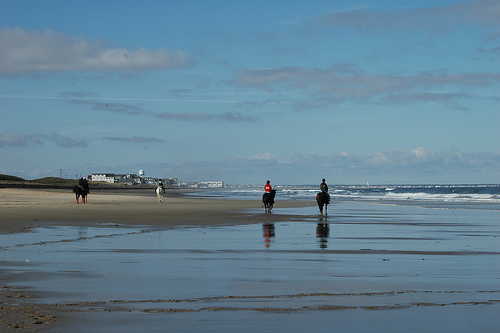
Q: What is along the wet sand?
A: Skid marks.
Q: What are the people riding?
A: Horses.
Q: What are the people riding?
A: Horses.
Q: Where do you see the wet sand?
A: Beach.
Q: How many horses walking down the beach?
A: Four.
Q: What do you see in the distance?
A: Mountain range.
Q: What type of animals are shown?
A: Horses.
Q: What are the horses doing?
A: Walking.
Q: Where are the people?
A: On the horses.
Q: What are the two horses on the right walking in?
A: Water.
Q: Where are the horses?
A: On the beach.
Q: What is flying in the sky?
A: Clouds.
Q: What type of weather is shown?
A: Partly cloudy.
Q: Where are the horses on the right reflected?
A: In the water.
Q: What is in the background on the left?
A: Hills.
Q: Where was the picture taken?
A: At the beach.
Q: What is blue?
A: Sky.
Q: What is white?
A: Clouds.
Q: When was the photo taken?
A: Daytime.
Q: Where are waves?
A: In the ocean.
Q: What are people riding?
A: Horses.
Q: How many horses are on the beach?
A: Four.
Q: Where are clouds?
A: In the sky.